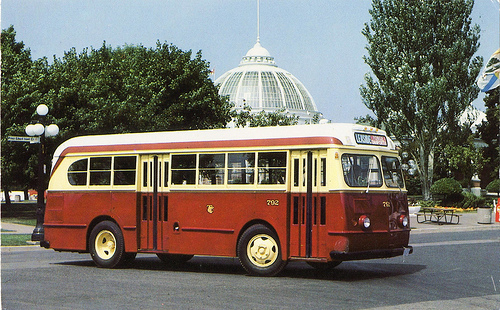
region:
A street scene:
[1, 5, 496, 305]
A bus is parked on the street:
[31, 112, 424, 277]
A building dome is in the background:
[211, 2, 321, 122]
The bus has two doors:
[127, 142, 333, 259]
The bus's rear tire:
[73, 211, 133, 277]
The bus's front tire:
[226, 216, 286, 279]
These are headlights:
[349, 205, 410, 233]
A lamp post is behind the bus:
[20, 94, 58, 245]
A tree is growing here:
[366, 1, 471, 217]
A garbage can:
[473, 197, 498, 235]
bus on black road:
[37, 126, 402, 274]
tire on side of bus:
[230, 220, 290, 272]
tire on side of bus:
[84, 222, 137, 269]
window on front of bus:
[336, 158, 376, 189]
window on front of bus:
[382, 155, 402, 186]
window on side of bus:
[257, 150, 283, 184]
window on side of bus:
[234, 151, 253, 178]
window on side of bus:
[196, 157, 222, 185]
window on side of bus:
[166, 145, 201, 186]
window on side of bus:
[111, 155, 138, 188]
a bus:
[94, 71, 394, 296]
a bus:
[142, 146, 294, 307]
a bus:
[136, 113, 338, 248]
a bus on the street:
[31, 122, 420, 284]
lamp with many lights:
[21, 97, 63, 246]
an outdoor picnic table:
[406, 198, 464, 232]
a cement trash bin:
[471, 200, 492, 230]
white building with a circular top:
[215, 39, 322, 126]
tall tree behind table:
[363, 0, 487, 228]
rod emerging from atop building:
[250, 0, 270, 70]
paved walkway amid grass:
[2, 204, 36, 247]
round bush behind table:
[425, 176, 471, 219]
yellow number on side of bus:
[261, 195, 283, 208]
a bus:
[241, 214, 371, 301]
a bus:
[334, 146, 338, 303]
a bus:
[207, 160, 315, 295]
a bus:
[140, 68, 268, 207]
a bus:
[264, 141, 344, 279]